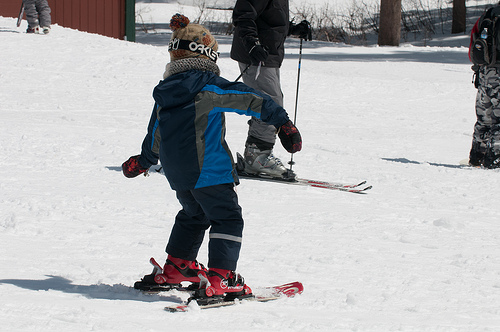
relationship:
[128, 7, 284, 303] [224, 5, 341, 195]
kid near person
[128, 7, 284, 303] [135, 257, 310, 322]
kid wearing skis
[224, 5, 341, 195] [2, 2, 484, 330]
person on snow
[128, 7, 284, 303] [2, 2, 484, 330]
kid on snow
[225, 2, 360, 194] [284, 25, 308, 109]
person holding ski poles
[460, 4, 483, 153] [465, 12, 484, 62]
person wearing black and red backpack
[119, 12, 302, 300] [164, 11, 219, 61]
child wearing beanie hat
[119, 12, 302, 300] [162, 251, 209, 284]
child wearing ski boot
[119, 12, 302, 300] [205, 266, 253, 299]
child wearing ski boot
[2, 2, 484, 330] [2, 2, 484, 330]
snow covering ground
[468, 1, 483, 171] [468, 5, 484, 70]
person wearing backpack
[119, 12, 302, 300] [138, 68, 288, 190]
child wearing jacket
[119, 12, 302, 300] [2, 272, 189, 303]
child casting shadow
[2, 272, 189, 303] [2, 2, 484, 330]
shadow casted on ground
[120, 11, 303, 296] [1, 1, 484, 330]
kid skiing in ski resort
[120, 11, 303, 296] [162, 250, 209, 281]
kid wearing ski shoe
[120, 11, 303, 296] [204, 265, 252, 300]
kid wearing ski shoe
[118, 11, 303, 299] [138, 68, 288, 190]
person wearing coat